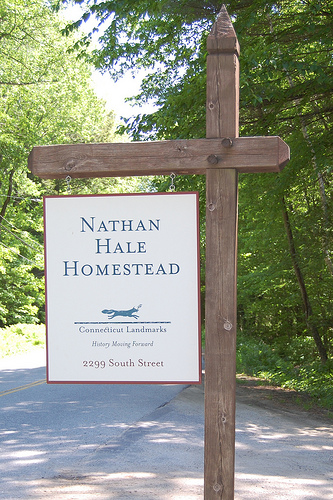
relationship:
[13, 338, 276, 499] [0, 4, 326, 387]
road near trees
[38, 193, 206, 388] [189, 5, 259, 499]
sign on post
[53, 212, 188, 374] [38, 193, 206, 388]
writing on sign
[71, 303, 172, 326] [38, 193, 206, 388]
logo on sign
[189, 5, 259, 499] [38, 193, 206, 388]
post on sign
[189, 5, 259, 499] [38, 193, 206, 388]
post holding sign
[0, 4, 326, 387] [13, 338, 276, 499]
trees near road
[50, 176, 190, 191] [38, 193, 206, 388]
chains holding sign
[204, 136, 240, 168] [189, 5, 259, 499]
bolts on post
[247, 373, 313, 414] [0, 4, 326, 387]
dirt near trees